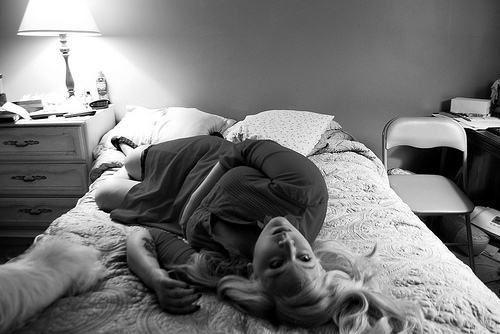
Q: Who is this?
A: A woman.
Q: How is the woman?
A: Motionless.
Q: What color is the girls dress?
A: Black.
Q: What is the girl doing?
A: Posing.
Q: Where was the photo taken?
A: In a bedroom.